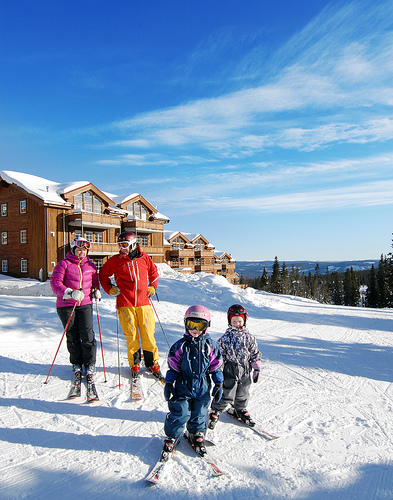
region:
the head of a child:
[179, 288, 231, 350]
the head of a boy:
[223, 280, 265, 347]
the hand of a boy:
[241, 353, 269, 395]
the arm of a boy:
[236, 326, 272, 388]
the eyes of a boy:
[219, 318, 256, 335]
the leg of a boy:
[220, 358, 280, 437]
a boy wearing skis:
[206, 390, 287, 439]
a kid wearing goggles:
[174, 312, 214, 344]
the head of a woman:
[62, 210, 101, 279]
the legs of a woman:
[54, 280, 107, 391]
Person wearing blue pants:
[164, 305, 220, 453]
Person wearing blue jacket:
[166, 307, 216, 454]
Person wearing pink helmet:
[166, 307, 218, 455]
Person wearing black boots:
[165, 305, 223, 456]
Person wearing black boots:
[213, 304, 257, 427]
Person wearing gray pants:
[216, 304, 261, 424]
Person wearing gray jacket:
[218, 305, 259, 427]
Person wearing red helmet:
[219, 302, 263, 427]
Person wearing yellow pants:
[100, 231, 165, 377]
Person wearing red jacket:
[100, 232, 161, 380]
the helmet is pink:
[181, 304, 210, 319]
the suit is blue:
[188, 360, 203, 380]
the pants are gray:
[227, 370, 233, 383]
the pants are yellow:
[119, 315, 139, 345]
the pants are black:
[79, 318, 92, 346]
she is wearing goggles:
[183, 315, 209, 334]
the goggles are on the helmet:
[226, 304, 248, 315]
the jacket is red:
[119, 266, 130, 285]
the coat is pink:
[63, 268, 75, 280]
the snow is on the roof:
[168, 227, 185, 239]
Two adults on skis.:
[45, 229, 165, 390]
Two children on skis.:
[143, 305, 279, 485]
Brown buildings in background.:
[7, 176, 249, 289]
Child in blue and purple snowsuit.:
[152, 303, 221, 467]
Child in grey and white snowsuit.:
[217, 303, 264, 425]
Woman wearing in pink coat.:
[38, 222, 109, 405]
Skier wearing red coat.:
[99, 232, 181, 403]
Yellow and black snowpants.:
[112, 302, 163, 363]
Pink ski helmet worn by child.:
[179, 303, 216, 322]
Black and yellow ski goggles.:
[180, 315, 208, 331]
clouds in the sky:
[184, 95, 312, 146]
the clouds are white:
[142, 114, 222, 141]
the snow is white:
[285, 383, 342, 452]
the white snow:
[287, 380, 374, 444]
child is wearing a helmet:
[185, 307, 209, 320]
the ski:
[256, 425, 276, 440]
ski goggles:
[71, 241, 95, 248]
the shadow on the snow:
[299, 329, 357, 373]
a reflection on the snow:
[27, 394, 75, 417]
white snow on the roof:
[24, 174, 43, 187]